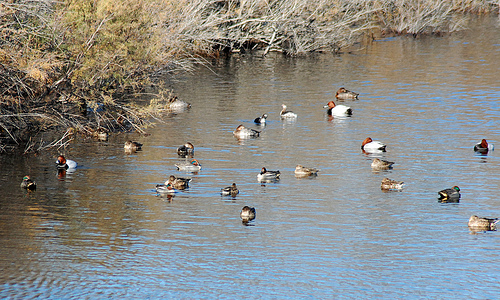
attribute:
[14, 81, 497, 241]
ducks — several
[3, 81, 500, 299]
water — still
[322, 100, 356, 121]
duck — white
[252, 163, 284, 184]
duck — grey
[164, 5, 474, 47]
branches — leafless, many, bare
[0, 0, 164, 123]
leaves — green-yellow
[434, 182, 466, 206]
duck — black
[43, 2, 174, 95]
leaves — green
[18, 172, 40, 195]
duck — black